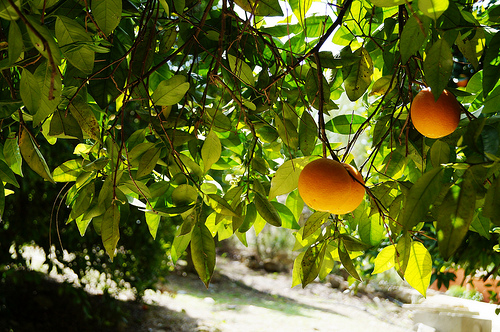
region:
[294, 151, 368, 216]
Round orange is hanging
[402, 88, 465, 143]
Round orange is hanging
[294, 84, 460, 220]
Two round oranges are hanging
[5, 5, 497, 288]
Leaves on a tree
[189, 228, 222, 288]
Leaf is green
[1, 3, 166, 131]
Leaves on a tree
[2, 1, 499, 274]
Leaves surrounding an orange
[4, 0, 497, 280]
Leaves surrounding two oranges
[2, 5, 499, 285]
Trees hanging over a road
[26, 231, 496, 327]
Road under trees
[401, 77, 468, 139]
ripe orange on a tree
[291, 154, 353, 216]
ripe orange on a tree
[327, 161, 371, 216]
ripe orange on a tree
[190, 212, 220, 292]
green orange tree leaf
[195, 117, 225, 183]
green orange tree leaf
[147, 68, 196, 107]
green orange tree leaf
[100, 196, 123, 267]
green orange tree leaf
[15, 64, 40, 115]
green orange tree leaf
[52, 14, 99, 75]
green orange tree leaf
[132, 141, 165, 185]
green orange tree leaf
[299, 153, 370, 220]
two oranges clustered together on a branch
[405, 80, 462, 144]
a single orange hanging from a branch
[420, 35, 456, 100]
dark green vertically pointed leaf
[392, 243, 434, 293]
yellow tinted leaf in sunlight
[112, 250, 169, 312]
plant root in ground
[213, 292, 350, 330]
dirt cast white by sunlight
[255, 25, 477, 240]
oranges in an orange grove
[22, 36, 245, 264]
heavy lush leaf vegetation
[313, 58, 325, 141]
dark brown branch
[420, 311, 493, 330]
dirty pooled water on the ground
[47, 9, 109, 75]
a green tree leaf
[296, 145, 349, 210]
an orange hanging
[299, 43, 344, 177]
small brown branch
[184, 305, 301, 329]
sunlight hitting the ground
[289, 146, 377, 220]
two oranges on a branch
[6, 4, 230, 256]
leaves and branches of a tree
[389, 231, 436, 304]
sunlight hitting a leaf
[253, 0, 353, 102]
thin branches of the tree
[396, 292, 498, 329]
puddle of water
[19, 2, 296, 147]
leaves shaded from the sun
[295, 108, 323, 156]
green orange tree leaf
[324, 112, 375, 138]
green orange tree leaf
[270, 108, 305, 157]
green orange tree leaf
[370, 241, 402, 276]
green orange tree leaf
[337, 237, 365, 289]
green orange tree leaf